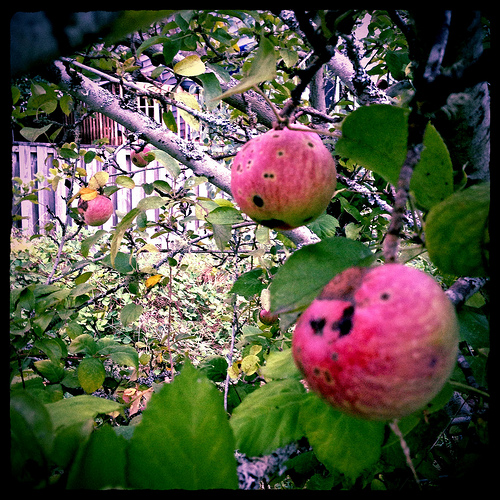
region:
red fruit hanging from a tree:
[272, 239, 457, 437]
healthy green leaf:
[127, 337, 239, 498]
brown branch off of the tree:
[151, 118, 252, 199]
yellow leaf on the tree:
[72, 180, 108, 210]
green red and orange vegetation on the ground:
[102, 282, 216, 404]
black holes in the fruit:
[297, 277, 364, 360]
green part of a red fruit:
[252, 173, 336, 250]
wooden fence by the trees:
[3, 128, 95, 257]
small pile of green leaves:
[3, 277, 141, 409]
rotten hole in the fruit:
[242, 180, 275, 218]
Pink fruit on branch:
[230, 117, 335, 227]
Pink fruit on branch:
[290, 260, 455, 414]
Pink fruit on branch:
[78, 192, 115, 223]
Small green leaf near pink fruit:
[302, 392, 388, 480]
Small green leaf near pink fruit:
[325, 101, 452, 216]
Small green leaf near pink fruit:
[227, 382, 310, 449]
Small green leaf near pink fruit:
[307, 216, 340, 236]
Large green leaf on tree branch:
[100, 246, 133, 271]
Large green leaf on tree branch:
[65, 333, 100, 350]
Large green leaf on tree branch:
[115, 300, 148, 327]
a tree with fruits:
[22, 8, 486, 492]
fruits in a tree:
[46, 86, 471, 423]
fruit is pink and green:
[286, 245, 474, 433]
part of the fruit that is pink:
[223, 113, 333, 203]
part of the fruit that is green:
[260, 205, 332, 235]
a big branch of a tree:
[56, 62, 213, 184]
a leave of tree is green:
[123, 355, 245, 494]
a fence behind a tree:
[14, 122, 251, 250]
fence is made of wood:
[16, 125, 200, 248]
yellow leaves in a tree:
[40, 155, 107, 199]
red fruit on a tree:
[277, 242, 459, 439]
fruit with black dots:
[249, 236, 451, 426]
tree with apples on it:
[40, 75, 433, 437]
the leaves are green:
[17, 225, 237, 470]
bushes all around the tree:
[14, 209, 231, 353]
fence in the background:
[8, 134, 186, 252]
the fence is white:
[0, 122, 199, 223]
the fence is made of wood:
[0, 127, 196, 231]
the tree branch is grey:
[92, 77, 212, 199]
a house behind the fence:
[48, 48, 215, 155]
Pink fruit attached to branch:
[228, 111, 336, 232]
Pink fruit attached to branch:
[289, 256, 461, 421]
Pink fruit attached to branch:
[75, 194, 116, 226]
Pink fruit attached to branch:
[127, 143, 153, 168]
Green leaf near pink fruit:
[128, 350, 239, 488]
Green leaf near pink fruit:
[298, 388, 385, 483]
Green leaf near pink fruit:
[331, 105, 456, 210]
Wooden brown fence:
[11, 137, 221, 238]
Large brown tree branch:
[52, 58, 330, 255]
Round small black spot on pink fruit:
[251, 188, 266, 210]